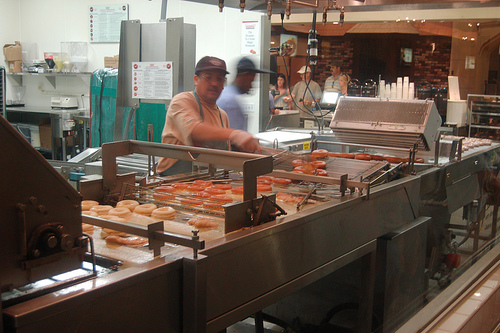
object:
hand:
[231, 130, 262, 154]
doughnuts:
[312, 149, 328, 158]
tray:
[272, 153, 390, 182]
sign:
[88, 3, 129, 43]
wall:
[4, 0, 265, 194]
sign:
[131, 61, 173, 99]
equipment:
[114, 16, 196, 141]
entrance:
[313, 33, 452, 126]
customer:
[274, 60, 351, 117]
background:
[268, 18, 500, 142]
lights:
[349, 0, 367, 6]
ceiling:
[180, 0, 499, 24]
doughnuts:
[153, 149, 425, 211]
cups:
[375, 76, 414, 99]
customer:
[273, 73, 291, 110]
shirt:
[291, 80, 322, 117]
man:
[319, 60, 344, 105]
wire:
[282, 56, 336, 133]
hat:
[195, 56, 229, 75]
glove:
[233, 130, 262, 154]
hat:
[297, 66, 312, 75]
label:
[302, 141, 310, 150]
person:
[283, 65, 323, 117]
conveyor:
[156, 56, 262, 177]